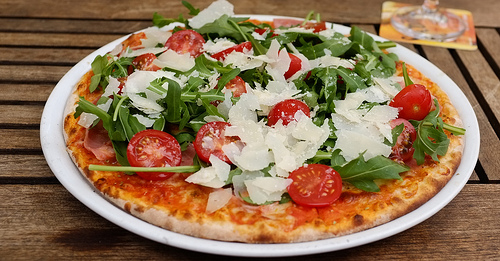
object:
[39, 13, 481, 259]
plate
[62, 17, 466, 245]
pizza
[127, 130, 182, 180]
tomato slice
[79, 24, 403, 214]
sliced cheese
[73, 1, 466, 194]
dandelions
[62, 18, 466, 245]
crust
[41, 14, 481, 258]
rim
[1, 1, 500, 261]
table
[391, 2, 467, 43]
glass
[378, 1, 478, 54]
coaster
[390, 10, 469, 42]
bottom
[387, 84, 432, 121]
tomato slices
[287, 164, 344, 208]
tomato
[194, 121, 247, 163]
vegetables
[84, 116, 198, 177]
sliced ham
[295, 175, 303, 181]
seeds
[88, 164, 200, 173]
stem